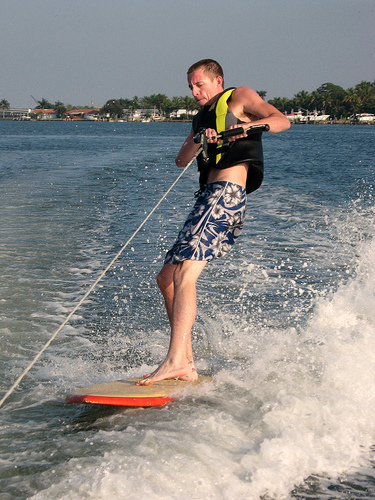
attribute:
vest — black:
[179, 105, 269, 175]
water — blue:
[0, 117, 374, 494]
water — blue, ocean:
[34, 177, 68, 206]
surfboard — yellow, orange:
[66, 368, 270, 406]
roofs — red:
[28, 104, 93, 114]